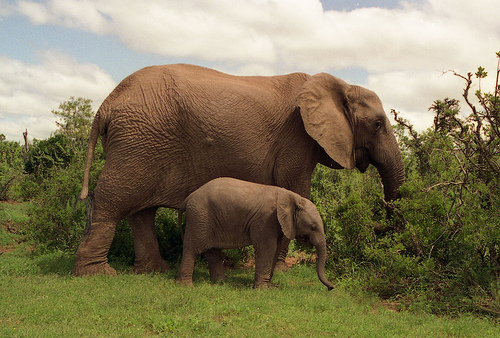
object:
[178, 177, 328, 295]
elephant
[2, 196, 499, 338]
grass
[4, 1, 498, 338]
shot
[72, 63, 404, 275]
elephant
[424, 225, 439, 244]
leaves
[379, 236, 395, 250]
leaves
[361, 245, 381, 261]
leaves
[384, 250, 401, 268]
leaves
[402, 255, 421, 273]
leaves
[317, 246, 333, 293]
trunk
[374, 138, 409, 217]
trunk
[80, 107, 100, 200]
tail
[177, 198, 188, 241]
tail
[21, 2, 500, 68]
cloud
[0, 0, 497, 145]
sky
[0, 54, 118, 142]
cloud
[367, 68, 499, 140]
cloud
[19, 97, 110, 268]
tree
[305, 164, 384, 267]
tree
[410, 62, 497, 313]
tree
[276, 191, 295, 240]
ear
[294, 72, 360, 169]
ear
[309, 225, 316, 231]
eye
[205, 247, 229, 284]
leg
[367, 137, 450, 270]
bushes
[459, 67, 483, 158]
branches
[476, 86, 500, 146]
branches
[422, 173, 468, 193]
branches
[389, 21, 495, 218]
air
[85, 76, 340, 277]
skin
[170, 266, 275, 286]
shadow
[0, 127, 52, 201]
plant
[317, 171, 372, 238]
plant